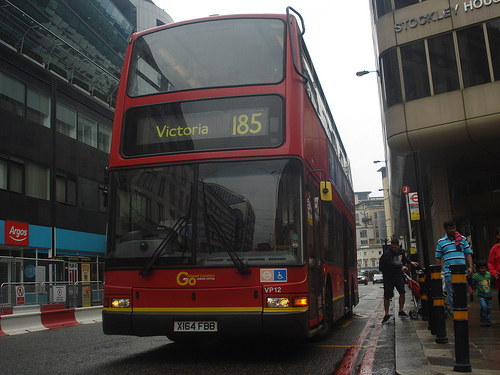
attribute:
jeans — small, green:
[475, 293, 499, 326]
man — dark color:
[434, 218, 473, 315]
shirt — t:
[435, 234, 473, 276]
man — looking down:
[380, 239, 407, 322]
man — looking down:
[438, 219, 473, 304]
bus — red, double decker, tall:
[100, 15, 360, 349]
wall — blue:
[16, 144, 98, 244]